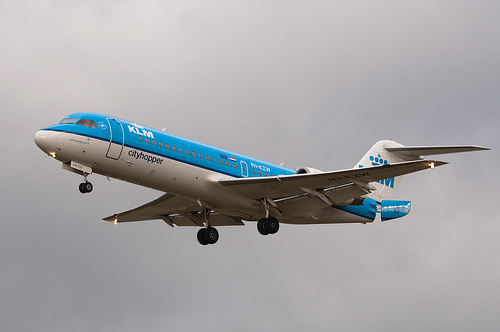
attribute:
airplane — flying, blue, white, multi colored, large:
[34, 112, 492, 245]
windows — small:
[138, 135, 275, 180]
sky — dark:
[0, 0, 499, 331]